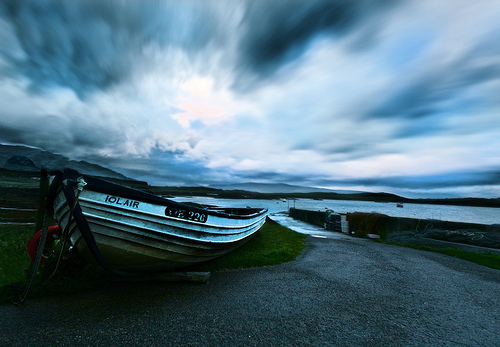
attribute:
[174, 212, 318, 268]
grass — green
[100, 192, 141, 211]
name — painted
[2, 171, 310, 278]
grass — green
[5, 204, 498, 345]
road — wet, dirt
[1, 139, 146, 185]
mountain range — background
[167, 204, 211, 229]
number — for licence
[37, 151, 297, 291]
boat — distant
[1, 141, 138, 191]
hills — rolling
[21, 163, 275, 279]
boat — with hitch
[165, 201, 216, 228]
numbers — white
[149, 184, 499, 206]
hillside — distant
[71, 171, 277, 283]
boat — white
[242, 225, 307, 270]
grass — green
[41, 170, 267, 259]
dirty boat — wooden, white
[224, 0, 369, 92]
cloud — black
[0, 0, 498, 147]
sky — overcast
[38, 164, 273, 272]
boat — ready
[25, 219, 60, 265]
light — red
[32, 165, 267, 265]
boat — behind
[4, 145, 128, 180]
mountain — grey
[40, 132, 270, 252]
boat — attached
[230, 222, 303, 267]
grass — green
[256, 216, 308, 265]
grass — green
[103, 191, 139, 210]
letters —  painted,  black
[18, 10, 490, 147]
sky —  grey,  overcast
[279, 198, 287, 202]
boat —  white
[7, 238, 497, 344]
road —  grey,  gravel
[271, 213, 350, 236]
ramp —  for boat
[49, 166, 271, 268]
boat —  white 